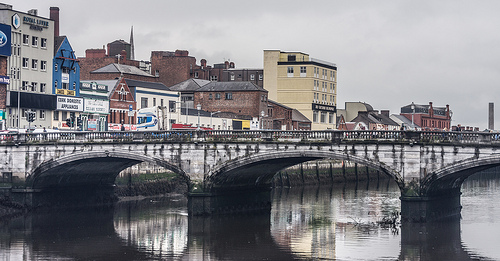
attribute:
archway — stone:
[116, 114, 460, 234]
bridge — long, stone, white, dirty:
[1, 132, 499, 196]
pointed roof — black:
[197, 80, 267, 94]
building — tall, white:
[0, 2, 53, 129]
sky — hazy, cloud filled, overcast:
[0, 1, 497, 131]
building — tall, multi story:
[198, 29, 400, 176]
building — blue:
[44, 5, 85, 133]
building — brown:
[259, 44, 330, 138]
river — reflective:
[1, 174, 496, 258]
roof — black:
[191, 78, 268, 94]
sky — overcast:
[362, 15, 380, 37]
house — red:
[391, 100, 456, 134]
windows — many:
[419, 111, 452, 127]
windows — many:
[140, 94, 180, 116]